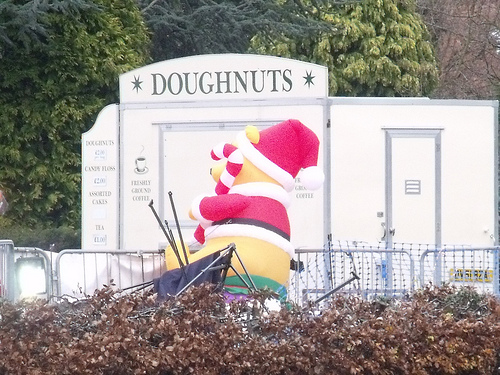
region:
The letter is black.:
[146, 69, 167, 98]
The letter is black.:
[164, 68, 183, 98]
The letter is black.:
[182, 69, 198, 96]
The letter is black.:
[197, 68, 217, 95]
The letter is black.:
[213, 66, 232, 95]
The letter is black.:
[231, 68, 251, 96]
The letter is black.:
[248, 65, 267, 93]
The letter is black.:
[265, 65, 282, 97]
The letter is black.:
[280, 65, 298, 93]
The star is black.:
[127, 72, 147, 97]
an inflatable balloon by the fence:
[144, 83, 344, 337]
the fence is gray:
[42, 235, 153, 312]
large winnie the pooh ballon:
[164, 104, 336, 311]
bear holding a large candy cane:
[161, 129, 238, 251]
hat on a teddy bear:
[243, 113, 335, 183]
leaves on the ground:
[68, 274, 471, 369]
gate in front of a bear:
[287, 248, 465, 287]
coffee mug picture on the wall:
[132, 153, 148, 179]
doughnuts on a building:
[155, 70, 290, 85]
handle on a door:
[377, 218, 402, 244]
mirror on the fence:
[9, 248, 55, 306]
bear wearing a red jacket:
[193, 189, 293, 249]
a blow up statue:
[162, 68, 412, 349]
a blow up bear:
[97, 33, 444, 349]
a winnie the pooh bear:
[172, 52, 392, 355]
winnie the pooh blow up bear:
[123, 36, 435, 364]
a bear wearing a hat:
[127, 128, 384, 308]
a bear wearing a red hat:
[136, 125, 353, 334]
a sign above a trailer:
[122, 33, 432, 267]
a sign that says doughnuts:
[89, 36, 458, 247]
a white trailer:
[79, 19, 440, 233]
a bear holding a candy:
[132, 108, 444, 370]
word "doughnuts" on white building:
[152, 68, 295, 99]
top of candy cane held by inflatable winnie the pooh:
[208, 141, 240, 193]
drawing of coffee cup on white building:
[126, 155, 151, 176]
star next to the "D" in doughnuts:
[125, 72, 146, 96]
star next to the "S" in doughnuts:
[295, 66, 319, 90]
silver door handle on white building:
[387, 226, 394, 240]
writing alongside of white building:
[82, 131, 117, 249]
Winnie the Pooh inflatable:
[164, 113, 321, 298]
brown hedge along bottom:
[1, 293, 496, 373]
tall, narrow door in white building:
[383, 125, 441, 293]